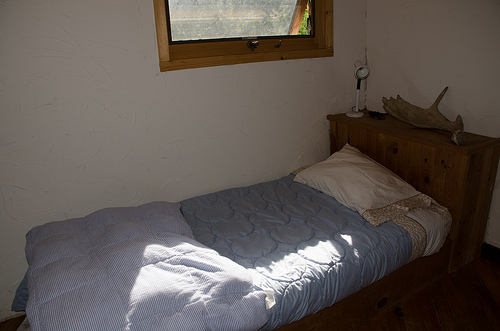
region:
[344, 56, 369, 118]
A small white lamp.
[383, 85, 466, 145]
The antler of an animal.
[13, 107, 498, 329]
A twin bed with a large headboard.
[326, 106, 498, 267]
The headboard is large enough to store items on it.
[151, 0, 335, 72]
An opened window above the bed.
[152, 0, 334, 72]
The window has a wooden frame.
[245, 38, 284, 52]
Part of the window's locking device.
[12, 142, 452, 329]
The bed has two blankets on it.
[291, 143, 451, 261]
The pillow case and the sheets match.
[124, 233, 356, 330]
Light, coming through the window, shining on the bed.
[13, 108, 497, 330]
a wooden bed in the corner of a room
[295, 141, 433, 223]
a white pillow with leopard patterns on the side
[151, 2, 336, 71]
a wooden window on the wall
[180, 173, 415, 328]
a blue bed-cover on a bed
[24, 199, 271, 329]
a blue duvet on a bed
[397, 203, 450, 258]
white sheets with leopard patterns on the side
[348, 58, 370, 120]
a white lamp on top of the bed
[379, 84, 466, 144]
a wooden branch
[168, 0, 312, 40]
a frosted window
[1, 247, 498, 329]
hardwood floor in a room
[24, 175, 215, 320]
blue blanket on the bed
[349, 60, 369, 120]
white lamp on the bed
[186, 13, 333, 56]
window partially open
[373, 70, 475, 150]
deer antler on the head board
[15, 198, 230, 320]
blanket on the foot of the bed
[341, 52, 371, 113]
lamp on the head board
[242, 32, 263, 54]
handle on the window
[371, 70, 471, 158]
antler on the head board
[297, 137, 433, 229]
Pillow on a bed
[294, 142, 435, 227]
Pillow is on a bed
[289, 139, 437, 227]
White pillow on a bed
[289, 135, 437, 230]
White pillow is on a bed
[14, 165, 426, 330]
Blanket on a bed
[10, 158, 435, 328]
Blanket is on a bed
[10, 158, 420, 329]
Blue blanket on a bed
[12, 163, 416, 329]
Blue blanket is on a bed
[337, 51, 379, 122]
Lamp on a shelf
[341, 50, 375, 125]
Lamp is on a shelf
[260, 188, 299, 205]
blue circle on blanket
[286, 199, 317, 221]
blue circle on blanket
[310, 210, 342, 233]
blue circle on blanket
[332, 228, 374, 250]
blue circle on blanket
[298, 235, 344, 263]
blue circle on blanket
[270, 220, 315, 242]
blue circle on blanket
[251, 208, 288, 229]
blue circle on blanket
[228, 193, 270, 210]
blue circle on blanket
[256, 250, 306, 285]
blue circle on blanket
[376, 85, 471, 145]
a piece of wood on a head board of a bed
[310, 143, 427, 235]
a pillow on a bed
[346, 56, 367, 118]
a small white lamp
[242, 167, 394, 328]
a bed covered with a blue blanket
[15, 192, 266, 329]
a blue blanket on a bed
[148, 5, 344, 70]
a wood framed window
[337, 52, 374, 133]
a lamp on a the head of a bed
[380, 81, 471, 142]
a piece of drift wood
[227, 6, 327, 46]
a opened window